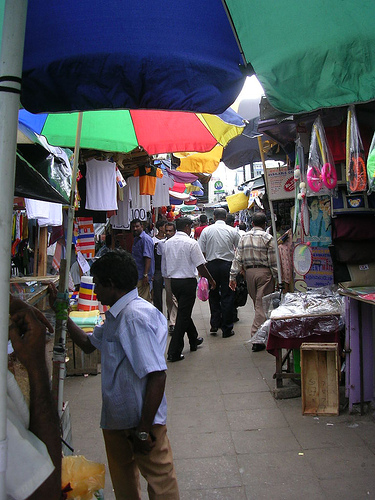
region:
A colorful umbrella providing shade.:
[8, 76, 254, 183]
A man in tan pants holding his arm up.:
[49, 239, 203, 498]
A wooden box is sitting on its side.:
[292, 329, 354, 431]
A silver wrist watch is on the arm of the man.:
[132, 424, 156, 447]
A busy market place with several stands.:
[1, 193, 374, 497]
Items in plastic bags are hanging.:
[276, 110, 374, 203]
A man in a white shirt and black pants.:
[156, 210, 215, 362]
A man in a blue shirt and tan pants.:
[124, 213, 166, 313]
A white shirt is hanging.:
[61, 150, 135, 229]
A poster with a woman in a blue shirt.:
[290, 185, 344, 256]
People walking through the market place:
[92, 204, 278, 496]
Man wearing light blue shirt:
[97, 289, 166, 426]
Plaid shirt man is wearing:
[227, 225, 276, 278]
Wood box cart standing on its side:
[297, 339, 336, 412]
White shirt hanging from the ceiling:
[82, 157, 116, 210]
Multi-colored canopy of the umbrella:
[15, 106, 247, 171]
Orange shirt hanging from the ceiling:
[135, 161, 161, 194]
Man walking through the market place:
[158, 215, 211, 360]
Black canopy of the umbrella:
[219, 115, 295, 167]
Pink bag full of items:
[196, 274, 208, 299]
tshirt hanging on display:
[73, 161, 119, 216]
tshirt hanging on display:
[134, 170, 159, 197]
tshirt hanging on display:
[119, 176, 150, 208]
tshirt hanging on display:
[160, 174, 176, 201]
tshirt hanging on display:
[122, 183, 132, 218]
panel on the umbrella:
[145, 109, 207, 151]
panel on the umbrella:
[70, 102, 136, 152]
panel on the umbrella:
[209, 116, 227, 135]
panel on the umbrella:
[30, 41, 211, 102]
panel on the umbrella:
[259, 11, 353, 95]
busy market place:
[17, 47, 355, 487]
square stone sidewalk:
[182, 369, 263, 495]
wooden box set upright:
[288, 336, 344, 416]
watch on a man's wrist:
[130, 420, 152, 444]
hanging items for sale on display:
[285, 105, 369, 195]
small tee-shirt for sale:
[128, 157, 159, 193]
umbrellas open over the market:
[86, 109, 286, 169]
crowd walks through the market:
[151, 188, 291, 353]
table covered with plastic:
[264, 288, 341, 345]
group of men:
[82, 204, 264, 393]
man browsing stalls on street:
[50, 258, 183, 486]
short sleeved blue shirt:
[73, 295, 168, 410]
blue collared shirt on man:
[63, 293, 185, 433]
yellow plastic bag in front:
[53, 456, 102, 496]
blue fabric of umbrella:
[21, 0, 222, 117]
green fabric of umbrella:
[233, 0, 370, 105]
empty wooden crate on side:
[296, 343, 340, 416]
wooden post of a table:
[270, 343, 291, 389]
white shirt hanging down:
[82, 157, 115, 217]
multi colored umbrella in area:
[40, 113, 236, 155]